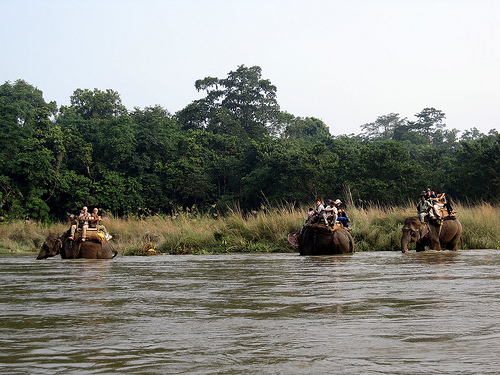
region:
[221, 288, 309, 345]
the water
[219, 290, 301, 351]
the water is brown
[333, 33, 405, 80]
the sky is clear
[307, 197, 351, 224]
people sitting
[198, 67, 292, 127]
the leaves are green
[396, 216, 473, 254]
the elephant is grey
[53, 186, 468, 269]
three grey elephants crossing the water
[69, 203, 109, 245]
seat on elephant transporting people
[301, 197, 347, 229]
seat on elephant transporting people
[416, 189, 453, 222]
seat on elephant transporting people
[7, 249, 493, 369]
body of water in jungle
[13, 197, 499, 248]
long grassy ban near water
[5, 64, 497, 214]
green lushy trees lining land near bank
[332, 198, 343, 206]
man wearing white hat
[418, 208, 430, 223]
Indian man wearing white pants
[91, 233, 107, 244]
yellow cushion on elephant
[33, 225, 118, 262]
The elephant furthest to the left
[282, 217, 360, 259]
The elephant in the middle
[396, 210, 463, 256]
The elephant furthest to the right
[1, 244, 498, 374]
The water that the elephants are in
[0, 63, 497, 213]
The trees beyond the grass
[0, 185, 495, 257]
The grass covering the water's bank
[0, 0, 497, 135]
The open sky visible above the trees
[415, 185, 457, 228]
People sitting atop the elephant on the right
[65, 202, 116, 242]
People sitting atop the elephant on the leftt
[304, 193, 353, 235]
People sitting atop the elephant in the middle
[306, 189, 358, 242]
people riding a elephant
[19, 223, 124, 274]
elephant crossing the river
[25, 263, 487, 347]
River moving calmly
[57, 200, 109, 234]
two people on top of a elephant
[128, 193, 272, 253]
tall grass near the river bank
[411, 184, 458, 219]
group of people on the elephant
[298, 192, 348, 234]
group of people on the elephant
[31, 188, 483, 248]
people crossing the river on the elephant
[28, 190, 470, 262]
people on the elephant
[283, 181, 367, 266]
people on top of a elephant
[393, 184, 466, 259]
people riding the elephant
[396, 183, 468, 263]
elephant in the water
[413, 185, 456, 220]
people riding an elephant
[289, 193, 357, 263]
elephant with people on it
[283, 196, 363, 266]
an elephant in the water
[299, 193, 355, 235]
people riding the elephant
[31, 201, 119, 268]
an elephant in the water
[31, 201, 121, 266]
people riding on the elephant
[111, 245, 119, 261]
a tail of the elephant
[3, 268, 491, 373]
a body of water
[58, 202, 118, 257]
people riding on elephant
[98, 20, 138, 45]
white clouds in blue sky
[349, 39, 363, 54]
white clouds in blue sky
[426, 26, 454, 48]
white clouds in blue sky